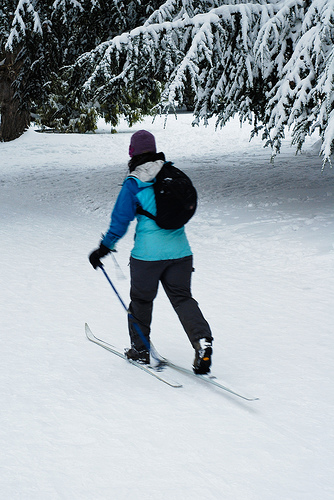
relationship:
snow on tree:
[147, 11, 320, 93] [13, 4, 327, 119]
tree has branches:
[13, 4, 327, 119] [129, 7, 332, 111]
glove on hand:
[85, 244, 117, 270] [91, 241, 125, 271]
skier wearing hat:
[90, 127, 221, 382] [127, 130, 156, 158]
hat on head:
[127, 130, 156, 158] [127, 126, 159, 160]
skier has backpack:
[90, 127, 221, 382] [145, 161, 199, 231]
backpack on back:
[145, 161, 199, 231] [137, 167, 193, 244]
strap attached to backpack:
[134, 204, 153, 222] [145, 161, 199, 231]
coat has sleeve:
[106, 166, 194, 263] [97, 176, 141, 245]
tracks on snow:
[209, 211, 267, 265] [38, 149, 86, 232]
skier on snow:
[90, 127, 221, 382] [38, 149, 86, 232]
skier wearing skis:
[90, 127, 221, 382] [78, 316, 264, 406]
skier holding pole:
[90, 127, 221, 382] [96, 258, 164, 367]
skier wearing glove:
[90, 127, 221, 382] [85, 244, 117, 270]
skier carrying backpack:
[90, 127, 221, 382] [145, 161, 199, 231]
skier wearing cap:
[90, 127, 221, 382] [125, 130, 159, 157]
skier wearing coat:
[90, 127, 221, 382] [106, 166, 194, 263]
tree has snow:
[13, 4, 327, 119] [147, 11, 320, 93]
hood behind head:
[127, 161, 167, 186] [127, 126, 159, 160]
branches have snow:
[129, 7, 332, 111] [147, 11, 320, 93]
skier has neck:
[90, 127, 221, 382] [129, 152, 166, 168]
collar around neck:
[123, 150, 171, 165] [129, 152, 166, 168]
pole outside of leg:
[96, 258, 164, 367] [122, 264, 156, 365]